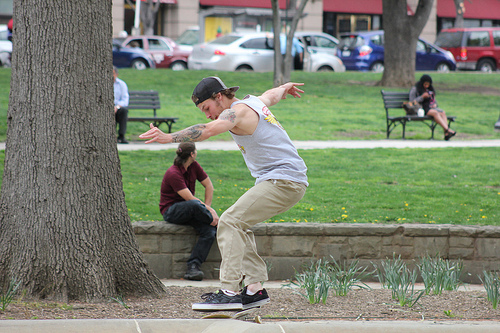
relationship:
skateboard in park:
[199, 306, 265, 323] [113, 70, 496, 221]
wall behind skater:
[133, 224, 497, 285] [137, 74, 309, 313]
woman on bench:
[411, 75, 457, 142] [381, 90, 453, 141]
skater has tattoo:
[137, 74, 309, 313] [170, 122, 206, 145]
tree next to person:
[0, 1, 164, 296] [158, 140, 220, 281]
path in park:
[117, 141, 499, 151] [113, 70, 496, 221]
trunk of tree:
[0, 10, 168, 304] [0, 1, 164, 296]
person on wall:
[158, 140, 220, 281] [133, 224, 497, 285]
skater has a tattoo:
[137, 74, 309, 313] [170, 122, 206, 145]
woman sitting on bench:
[411, 75, 457, 142] [381, 90, 453, 141]